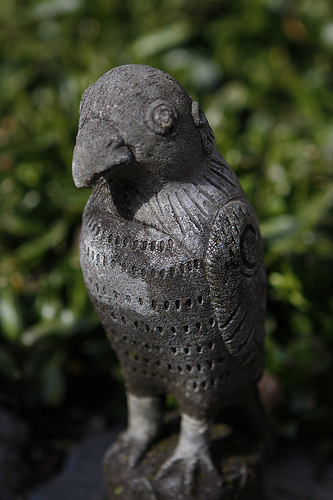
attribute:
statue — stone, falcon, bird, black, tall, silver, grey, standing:
[68, 65, 269, 480]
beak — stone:
[72, 124, 130, 192]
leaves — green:
[4, 13, 333, 455]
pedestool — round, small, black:
[101, 425, 264, 499]